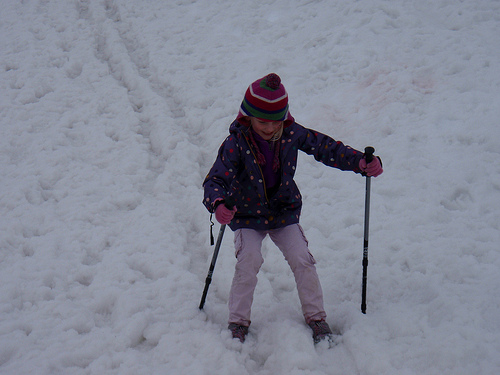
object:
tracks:
[100, 41, 224, 183]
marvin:
[237, 68, 292, 126]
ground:
[386, 130, 408, 151]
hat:
[238, 73, 293, 128]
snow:
[0, 0, 500, 375]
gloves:
[213, 198, 237, 225]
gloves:
[359, 154, 384, 177]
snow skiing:
[193, 70, 388, 347]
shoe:
[307, 319, 334, 349]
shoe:
[227, 321, 248, 345]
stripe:
[247, 81, 287, 103]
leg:
[271, 223, 328, 321]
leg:
[228, 227, 265, 328]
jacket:
[202, 123, 382, 231]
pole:
[362, 145, 378, 314]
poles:
[199, 197, 238, 311]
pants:
[229, 222, 328, 326]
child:
[201, 71, 383, 349]